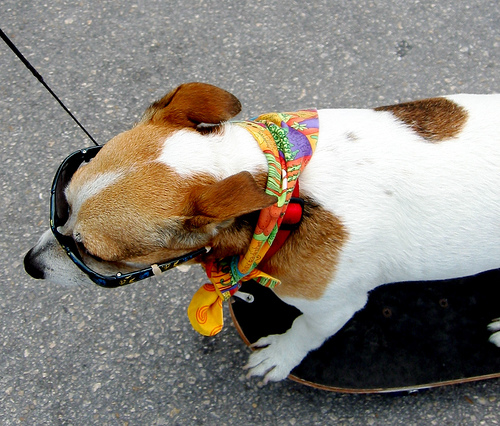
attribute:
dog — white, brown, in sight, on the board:
[25, 86, 499, 328]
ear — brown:
[200, 172, 276, 211]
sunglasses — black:
[44, 147, 147, 283]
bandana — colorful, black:
[239, 106, 313, 268]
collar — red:
[256, 190, 310, 256]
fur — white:
[319, 117, 487, 245]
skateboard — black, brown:
[218, 286, 498, 398]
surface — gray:
[3, 16, 470, 403]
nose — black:
[19, 241, 44, 282]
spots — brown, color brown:
[380, 90, 468, 143]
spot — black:
[343, 127, 363, 147]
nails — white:
[246, 338, 267, 383]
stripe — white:
[157, 131, 265, 175]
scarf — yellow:
[184, 275, 247, 332]